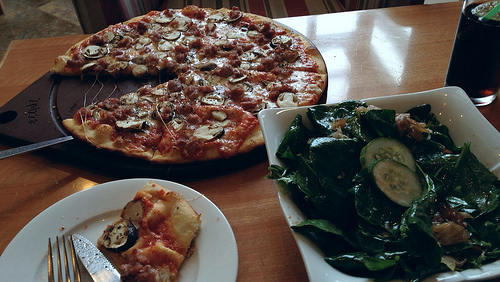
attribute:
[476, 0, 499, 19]
straw — green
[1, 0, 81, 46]
tiles — styled, granite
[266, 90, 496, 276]
salad — on table, spinach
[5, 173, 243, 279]
plate — white, square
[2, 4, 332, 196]
pan — round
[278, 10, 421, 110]
light — on table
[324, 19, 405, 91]
reflection — metal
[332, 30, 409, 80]
table — wooden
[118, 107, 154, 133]
mushrooms — on pizza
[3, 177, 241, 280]
dish — on table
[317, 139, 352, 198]
spinach — cooked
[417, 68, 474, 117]
bowl — white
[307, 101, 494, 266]
salad — green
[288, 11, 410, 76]
table — wood grain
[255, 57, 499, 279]
bowl — on table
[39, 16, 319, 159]
pizza — on table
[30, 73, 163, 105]
pan — skillet-like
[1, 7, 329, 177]
plate — dark brown